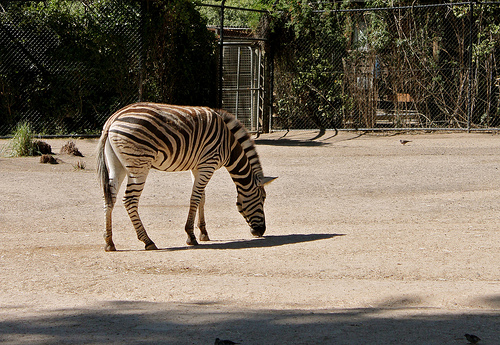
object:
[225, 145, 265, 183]
neck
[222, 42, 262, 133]
gate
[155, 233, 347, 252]
shadow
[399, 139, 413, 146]
bird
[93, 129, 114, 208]
tail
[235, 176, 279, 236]
head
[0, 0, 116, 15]
bush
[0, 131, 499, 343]
sand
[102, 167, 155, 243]
legs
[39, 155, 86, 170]
dirt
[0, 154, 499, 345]
gravel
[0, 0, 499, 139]
fence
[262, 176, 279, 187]
ear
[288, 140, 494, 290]
paved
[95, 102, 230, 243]
body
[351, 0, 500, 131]
vines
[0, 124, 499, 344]
ground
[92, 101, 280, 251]
zebra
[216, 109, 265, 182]
mane